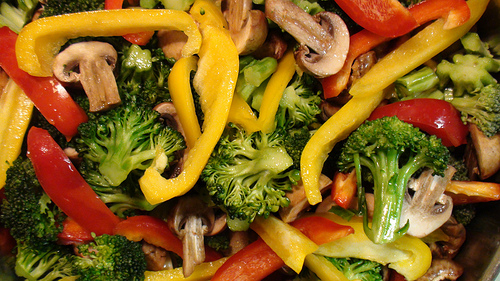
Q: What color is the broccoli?
A: Green.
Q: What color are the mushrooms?
A: Brown.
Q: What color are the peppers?
A: Yellow and red.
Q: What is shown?
A: A bowl of vegetables.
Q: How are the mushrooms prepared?
A: They are sliced.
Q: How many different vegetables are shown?
A: Three.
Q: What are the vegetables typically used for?
A: Stir fry.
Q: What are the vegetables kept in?
A: A bowl.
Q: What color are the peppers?
A: Red and yellow.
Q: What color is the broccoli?
A: Green.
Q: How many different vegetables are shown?
A: Three.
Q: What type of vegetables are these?
A: Stirfry.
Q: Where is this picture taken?
A: A kitchen.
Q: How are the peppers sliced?
A: Thinly.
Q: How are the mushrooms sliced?
A: Thinly.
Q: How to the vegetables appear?
A: Raw.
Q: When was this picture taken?
A: Before cooking.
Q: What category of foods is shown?
A: Vegetables.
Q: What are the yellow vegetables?
A: Peppers.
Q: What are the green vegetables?
A: Broccoli.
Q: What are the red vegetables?
A: Peppers.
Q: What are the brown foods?
A: Mushrooms.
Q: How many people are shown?
A: Zero.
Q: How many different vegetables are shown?
A: Four.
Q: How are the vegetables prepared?
A: Cut and sliced.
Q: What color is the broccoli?
A: Green.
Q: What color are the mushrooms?
A: Brown.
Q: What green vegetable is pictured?
A: Broccoli.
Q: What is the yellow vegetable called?
A: Yellow bell pepper.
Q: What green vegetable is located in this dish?
A: Broccoli.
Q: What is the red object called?
A: Red bell pepper.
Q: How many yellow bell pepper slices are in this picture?
A: 10.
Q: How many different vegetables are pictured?
A: 4.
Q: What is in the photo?
A: Vegetables.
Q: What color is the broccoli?
A: Green.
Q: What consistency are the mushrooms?
A: Soft.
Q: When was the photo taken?
A: At noon.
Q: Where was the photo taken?
A: In the kitchen.